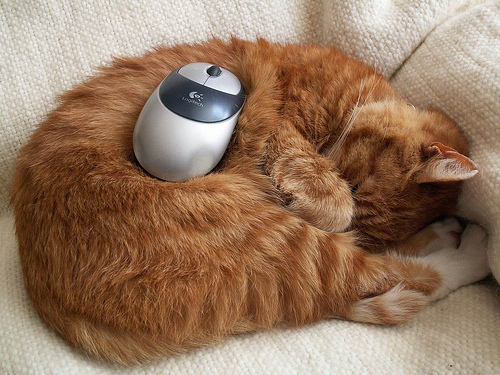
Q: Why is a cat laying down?
A: To sleep.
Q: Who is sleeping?
A: A cat.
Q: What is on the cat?
A: A mouse.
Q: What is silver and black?
A: Computer mouse.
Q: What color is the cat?
A: Light brown.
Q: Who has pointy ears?
A: The cat.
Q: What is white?
A: Cat's paws.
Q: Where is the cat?
A: Living room.